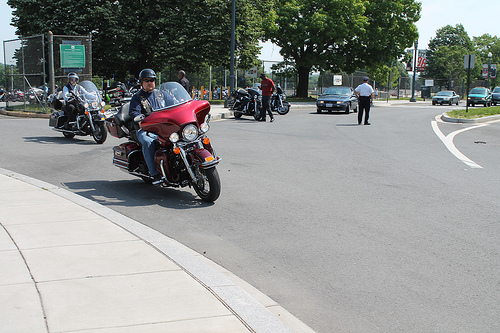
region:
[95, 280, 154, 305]
sidewalk made of concrete.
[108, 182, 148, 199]
shadow on the street.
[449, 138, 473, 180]
white line in the street.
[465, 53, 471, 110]
traffic sign on pole.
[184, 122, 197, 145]
headlight on the motorcycle.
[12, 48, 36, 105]
fencing near the street.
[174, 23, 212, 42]
leaves on the tree.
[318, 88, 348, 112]
car driving in the street.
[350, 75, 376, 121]
officer directing the traffic.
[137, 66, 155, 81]
helmet on man's head.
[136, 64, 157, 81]
Person wearing black helmet.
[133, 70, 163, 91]
Sunglasses on person's face.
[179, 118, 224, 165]
Large light on front of bike.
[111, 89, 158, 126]
Person wearing dark shirt.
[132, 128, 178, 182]
Person wearing blue jeans.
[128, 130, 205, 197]
Person riding on motorcycle.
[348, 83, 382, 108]
Person wearing white shirt.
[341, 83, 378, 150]
Person standing in street.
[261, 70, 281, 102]
Person wearing red shirt.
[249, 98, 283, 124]
Person wearing black pants.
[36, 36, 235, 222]
Two men on motorcycles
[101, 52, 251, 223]
Man on red motorcycle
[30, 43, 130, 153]
Man on black motorcycle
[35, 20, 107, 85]
Green and white streetsign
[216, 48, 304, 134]
Man standing by motorcycle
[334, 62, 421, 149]
Man standing in the street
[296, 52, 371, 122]
Black cat driving down street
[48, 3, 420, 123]
Trees with green leaves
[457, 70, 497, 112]
Green and black van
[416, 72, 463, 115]
Black car at stop sign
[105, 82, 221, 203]
a red motorcycle on street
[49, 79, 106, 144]
a black motorcycle on street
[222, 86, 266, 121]
a black motorcycle on street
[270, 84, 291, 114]
a black parked motorcycle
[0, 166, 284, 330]
a paved city sidewalk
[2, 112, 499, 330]
a paved city street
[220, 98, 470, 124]
a paved city street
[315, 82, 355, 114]
a black car in street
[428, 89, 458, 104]
a green car in street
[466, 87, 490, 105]
a blue van in street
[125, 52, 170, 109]
man wearing black helmet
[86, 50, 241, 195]
man wearing black shirt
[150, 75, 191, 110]
window on motor cycle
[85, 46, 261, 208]
red motor cycle riding down street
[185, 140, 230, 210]
tire on motor cycle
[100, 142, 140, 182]
storage on a motor cycle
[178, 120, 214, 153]
head light on motor cycle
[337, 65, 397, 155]
man wearing blue shirt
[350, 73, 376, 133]
man wearing uniform pants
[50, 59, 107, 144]
man wearing riding a motor cycle